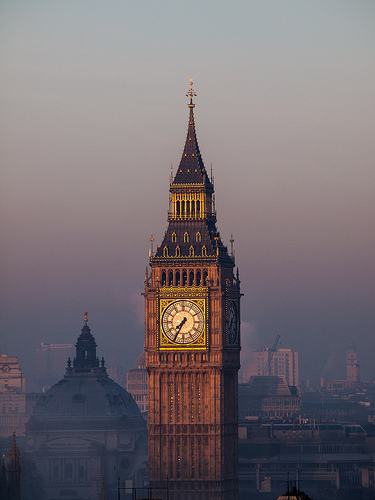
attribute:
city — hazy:
[26, 224, 319, 493]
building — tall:
[344, 340, 359, 399]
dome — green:
[345, 341, 355, 350]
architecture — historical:
[134, 72, 247, 498]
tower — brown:
[114, 58, 322, 489]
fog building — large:
[343, 346, 363, 381]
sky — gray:
[15, 8, 373, 75]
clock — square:
[145, 284, 213, 352]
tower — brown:
[140, 75, 242, 494]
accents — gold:
[170, 190, 205, 217]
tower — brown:
[86, 177, 285, 457]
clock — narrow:
[226, 301, 236, 343]